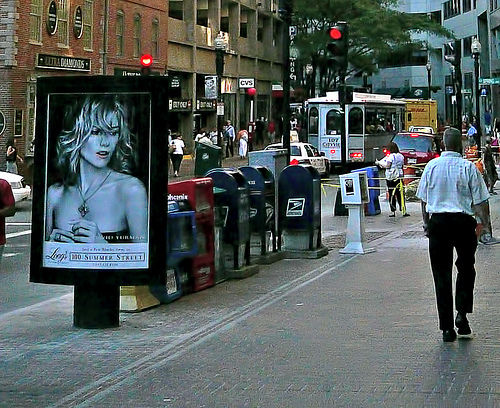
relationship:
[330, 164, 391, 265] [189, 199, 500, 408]
newstand on sidewalk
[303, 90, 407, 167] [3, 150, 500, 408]
trolley on road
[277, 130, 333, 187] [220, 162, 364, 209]
cab on street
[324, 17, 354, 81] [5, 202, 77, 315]
light on street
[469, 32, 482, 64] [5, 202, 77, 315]
light on street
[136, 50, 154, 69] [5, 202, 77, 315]
light on street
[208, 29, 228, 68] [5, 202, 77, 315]
light on street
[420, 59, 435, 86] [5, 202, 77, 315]
light on street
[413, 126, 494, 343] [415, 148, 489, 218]
man wearing shirt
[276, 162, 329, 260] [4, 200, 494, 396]
mail box on sidewalk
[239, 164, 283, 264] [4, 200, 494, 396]
mailbox on sidewalk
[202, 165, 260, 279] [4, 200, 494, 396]
mailbox on sidewalk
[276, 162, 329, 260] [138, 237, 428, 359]
mail box on sidewalk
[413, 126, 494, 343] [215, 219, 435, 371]
man on sidewalk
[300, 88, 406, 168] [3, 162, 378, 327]
trolley on road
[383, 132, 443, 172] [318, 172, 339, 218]
red van driving on road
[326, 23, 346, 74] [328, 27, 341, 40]
light with red light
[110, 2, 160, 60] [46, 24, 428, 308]
windows on a building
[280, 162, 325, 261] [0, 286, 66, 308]
mail box near curb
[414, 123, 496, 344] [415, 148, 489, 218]
man in shirt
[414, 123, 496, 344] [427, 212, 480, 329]
man in pants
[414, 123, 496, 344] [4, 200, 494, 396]
man walking down sidewalk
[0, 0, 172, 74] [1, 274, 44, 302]
buildings on a street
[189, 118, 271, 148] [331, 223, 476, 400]
people walking down sidewalk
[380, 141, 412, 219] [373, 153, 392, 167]
woman reading newspaper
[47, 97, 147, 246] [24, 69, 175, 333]
woman's photo on advertisement board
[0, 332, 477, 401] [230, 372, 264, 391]
sidewalk made from bricks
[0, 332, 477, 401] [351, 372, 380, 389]
sidewalk made from bricks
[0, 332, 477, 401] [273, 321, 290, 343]
sidewalk made from bricks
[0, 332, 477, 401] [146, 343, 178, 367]
sidewalk made from bricks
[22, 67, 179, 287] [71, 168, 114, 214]
woman wearing necklace